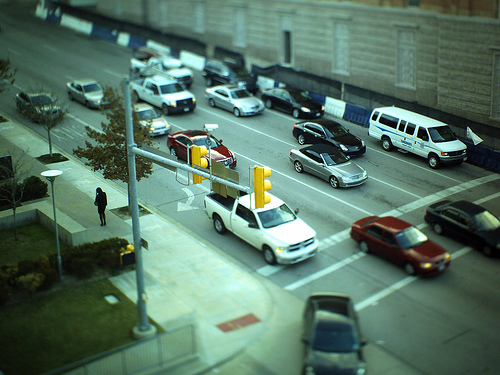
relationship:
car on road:
[289, 144, 368, 189] [0, 7, 483, 337]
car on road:
[300, 293, 369, 374] [3, 7, 483, 372]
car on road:
[349, 214, 451, 278] [3, 7, 483, 372]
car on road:
[424, 199, 499, 259] [3, 7, 483, 372]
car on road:
[203, 191, 320, 266] [0, 7, 483, 337]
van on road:
[367, 106, 468, 169] [3, 7, 483, 372]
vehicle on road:
[161, 125, 241, 178] [0, 7, 483, 337]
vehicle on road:
[14, 88, 68, 128] [3, 7, 483, 372]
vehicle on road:
[58, 70, 116, 114] [0, 7, 483, 337]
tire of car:
[353, 238, 373, 258] [345, 209, 455, 284]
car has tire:
[289, 144, 368, 189] [326, 172, 336, 191]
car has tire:
[289, 132, 368, 191] [293, 161, 302, 171]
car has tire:
[203, 80, 265, 118] [207, 97, 215, 110]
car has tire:
[203, 83, 266, 118] [231, 103, 242, 119]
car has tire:
[424, 199, 499, 259] [430, 218, 445, 238]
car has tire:
[423, 194, 499, 263] [477, 243, 493, 257]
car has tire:
[350, 213, 453, 279] [402, 258, 417, 276]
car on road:
[349, 214, 451, 278] [0, 0, 500, 375]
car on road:
[204, 185, 318, 270] [0, 0, 500, 375]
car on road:
[302, 288, 366, 374] [0, 0, 500, 375]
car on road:
[289, 144, 368, 189] [0, 0, 500, 375]